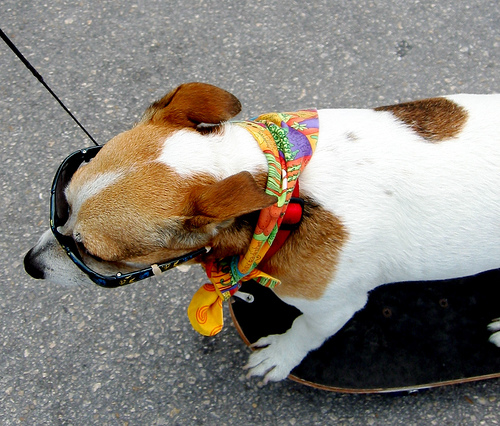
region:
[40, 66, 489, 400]
top of dog on skateboard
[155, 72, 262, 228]
ears on dogs head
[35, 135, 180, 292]
sunglasses on dog's face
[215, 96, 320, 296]
bandana on dog's neck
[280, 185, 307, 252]
red collar on dog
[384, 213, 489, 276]
white fur on torso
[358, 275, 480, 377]
black top of skateboard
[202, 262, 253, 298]
knot on colorful bandana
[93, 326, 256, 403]
gray pebbled surface under skateboard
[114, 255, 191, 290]
design on arm of sunglasses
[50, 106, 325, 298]
the dog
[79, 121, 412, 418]
the dog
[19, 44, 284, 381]
the dog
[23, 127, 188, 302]
dog is wearing glasses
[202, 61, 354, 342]
dog has multicolor bandanna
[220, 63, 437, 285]
dog is brown and white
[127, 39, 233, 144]
dog has brown ears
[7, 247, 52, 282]
dog has black nose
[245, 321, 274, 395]
dog has white paws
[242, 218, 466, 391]
dog is on skateboard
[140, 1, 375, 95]
speckled pavement beneath dog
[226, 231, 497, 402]
skateboard is black and brown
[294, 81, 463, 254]
brown spots on back of dog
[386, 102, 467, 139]
brown spot on dogs fur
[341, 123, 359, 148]
black spot on dogs fur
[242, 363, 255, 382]
dog has white nails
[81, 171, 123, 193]
white stripe on dogs head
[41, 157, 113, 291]
dog is wearing black shades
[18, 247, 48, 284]
dogs nose is black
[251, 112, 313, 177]
colorful scarf on dogs neck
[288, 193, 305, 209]
black stripe on scarf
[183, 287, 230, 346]
yellow bowtie at end of scarf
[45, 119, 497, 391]
dog riding a skateboard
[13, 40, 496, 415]
The dog is on the skateboard.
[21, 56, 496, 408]
The dog is brown and white.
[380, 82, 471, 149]
A brown spot on the dog.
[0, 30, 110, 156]
The dog is on a leash.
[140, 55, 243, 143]
The dog has a brown ear.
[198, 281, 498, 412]
The skateboard is black.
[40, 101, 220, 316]
The dog is wearing sunglasses.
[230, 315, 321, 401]
The dog's leg is white.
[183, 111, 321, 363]
The dog is wearing a multicolored scarf.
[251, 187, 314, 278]
The dog has a red collar.